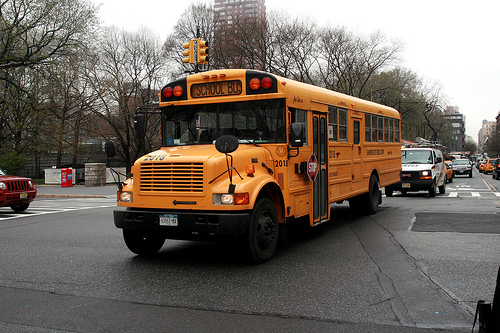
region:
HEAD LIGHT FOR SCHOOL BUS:
[213, 191, 251, 206]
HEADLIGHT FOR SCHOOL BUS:
[113, 183, 137, 210]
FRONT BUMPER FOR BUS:
[116, 202, 259, 241]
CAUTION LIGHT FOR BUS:
[244, 69, 279, 101]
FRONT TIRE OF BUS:
[245, 191, 295, 267]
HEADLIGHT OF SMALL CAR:
[420, 168, 433, 180]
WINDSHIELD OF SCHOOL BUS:
[224, 100, 287, 146]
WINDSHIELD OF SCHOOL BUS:
[156, 111, 208, 141]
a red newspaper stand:
[57, 167, 72, 187]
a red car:
[1, 170, 32, 207]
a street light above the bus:
[180, 35, 210, 60]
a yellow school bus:
[110, 67, 400, 252]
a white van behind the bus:
[400, 145, 445, 190]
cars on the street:
[401, 140, 496, 200]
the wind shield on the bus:
[162, 105, 282, 140]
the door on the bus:
[310, 111, 325, 216]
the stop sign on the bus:
[301, 151, 316, 176]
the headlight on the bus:
[216, 192, 236, 203]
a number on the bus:
[273, 158, 290, 168]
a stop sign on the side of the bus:
[306, 154, 318, 179]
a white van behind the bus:
[401, 144, 448, 194]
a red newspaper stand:
[61, 168, 73, 186]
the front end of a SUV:
[0, 173, 35, 210]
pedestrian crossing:
[435, 190, 497, 197]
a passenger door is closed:
[312, 111, 329, 223]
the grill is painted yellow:
[137, 163, 204, 193]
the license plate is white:
[156, 214, 177, 226]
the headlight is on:
[420, 170, 432, 178]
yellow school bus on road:
[112, 49, 419, 279]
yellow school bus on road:
[112, 45, 434, 267]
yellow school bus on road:
[130, 63, 405, 261]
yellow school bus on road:
[103, 23, 428, 288]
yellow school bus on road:
[108, 36, 413, 314]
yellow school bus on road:
[115, 38, 426, 299]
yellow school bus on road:
[100, 35, 425, 293]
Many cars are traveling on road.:
[0, 67, 498, 332]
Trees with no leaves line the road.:
[0, 0, 465, 183]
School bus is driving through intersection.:
[0, 67, 498, 332]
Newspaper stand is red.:
[58, 166, 73, 187]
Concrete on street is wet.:
[1, 151, 497, 331]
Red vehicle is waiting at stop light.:
[0, 37, 212, 217]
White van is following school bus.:
[101, 72, 446, 267]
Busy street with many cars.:
[0, 1, 498, 331]